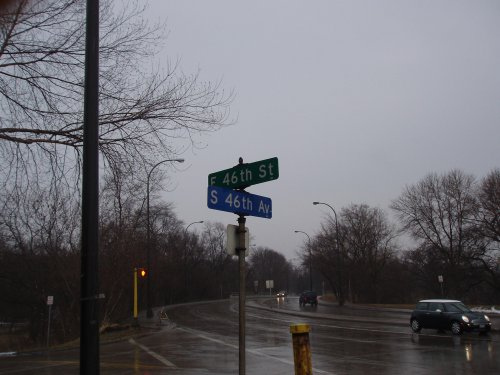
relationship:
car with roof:
[409, 298, 493, 335] [411, 285, 463, 310]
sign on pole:
[205, 155, 280, 374] [288, 322, 315, 374]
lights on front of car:
[277, 290, 284, 295] [276, 291, 288, 297]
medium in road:
[245, 293, 412, 328] [180, 291, 487, 374]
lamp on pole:
[139, 265, 150, 278] [130, 263, 138, 320]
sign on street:
[202, 150, 280, 359] [260, 276, 277, 303]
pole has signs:
[216, 234, 276, 374] [131, 136, 303, 240]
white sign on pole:
[48, 296, 54, 306] [44, 305, 51, 337]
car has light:
[275, 287, 289, 299] [282, 292, 285, 295]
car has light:
[275, 287, 289, 299] [275, 290, 280, 294]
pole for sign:
[236, 216, 248, 375] [205, 155, 280, 374]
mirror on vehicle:
[430, 305, 443, 315] [405, 290, 484, 340]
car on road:
[409, 298, 493, 335] [91, 283, 499, 373]